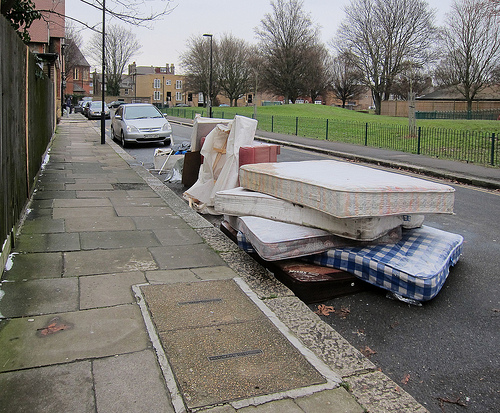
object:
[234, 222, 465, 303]
mattress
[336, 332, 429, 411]
curb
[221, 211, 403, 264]
mattresses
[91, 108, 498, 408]
road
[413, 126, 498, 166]
fence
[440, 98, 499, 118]
fence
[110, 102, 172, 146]
car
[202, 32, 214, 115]
street light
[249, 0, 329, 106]
trees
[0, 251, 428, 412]
sidewalk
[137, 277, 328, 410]
slabs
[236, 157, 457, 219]
mattress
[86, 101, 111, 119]
car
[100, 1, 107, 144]
pole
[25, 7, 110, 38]
branch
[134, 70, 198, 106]
building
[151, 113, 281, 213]
garbage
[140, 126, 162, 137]
grill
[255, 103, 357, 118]
grass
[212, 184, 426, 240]
mattress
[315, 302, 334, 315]
leaf